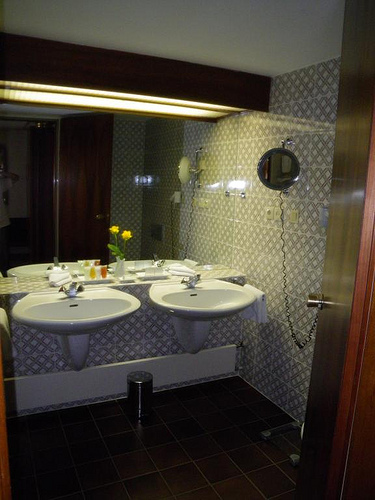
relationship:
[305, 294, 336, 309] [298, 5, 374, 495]
door handle part of door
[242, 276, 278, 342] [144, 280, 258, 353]
towel beside sink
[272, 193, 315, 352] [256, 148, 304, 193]
cord hanging from mirror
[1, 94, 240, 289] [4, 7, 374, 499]
mirror in bathroom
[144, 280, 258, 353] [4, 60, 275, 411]
sink to wall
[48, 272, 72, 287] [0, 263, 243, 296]
washrags on ledge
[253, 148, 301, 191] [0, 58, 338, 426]
mirror on wall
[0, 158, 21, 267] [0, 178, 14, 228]
person in shirt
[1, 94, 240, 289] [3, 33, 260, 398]
mirror on wall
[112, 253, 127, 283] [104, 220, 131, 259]
vase with flower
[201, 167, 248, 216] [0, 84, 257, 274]
light reflecting in mirror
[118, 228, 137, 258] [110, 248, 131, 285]
flower in a vase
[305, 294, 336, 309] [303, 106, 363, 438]
door handle on door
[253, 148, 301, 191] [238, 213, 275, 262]
mirror on a wall